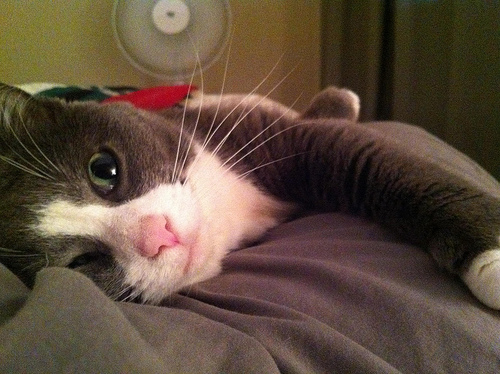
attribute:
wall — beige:
[0, 7, 350, 112]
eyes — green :
[64, 146, 124, 266]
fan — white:
[111, 1, 238, 80]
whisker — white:
[151, 102, 293, 204]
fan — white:
[104, 2, 246, 102]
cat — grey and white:
[1, 63, 498, 338]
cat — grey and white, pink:
[1, 77, 499, 314]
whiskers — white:
[178, 61, 316, 187]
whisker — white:
[178, 38, 271, 187]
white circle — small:
[150, 1, 189, 34]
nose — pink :
[126, 212, 180, 259]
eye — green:
[85, 146, 118, 195]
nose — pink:
[123, 203, 185, 259]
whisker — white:
[171, 38, 301, 195]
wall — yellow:
[3, 0, 323, 110]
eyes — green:
[77, 133, 136, 188]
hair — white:
[172, 88, 311, 222]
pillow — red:
[94, 74, 263, 135]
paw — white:
[468, 240, 498, 303]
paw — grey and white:
[418, 197, 497, 318]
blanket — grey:
[96, 105, 475, 370]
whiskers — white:
[144, 104, 302, 204]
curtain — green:
[320, 31, 491, 118]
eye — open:
[82, 143, 125, 194]